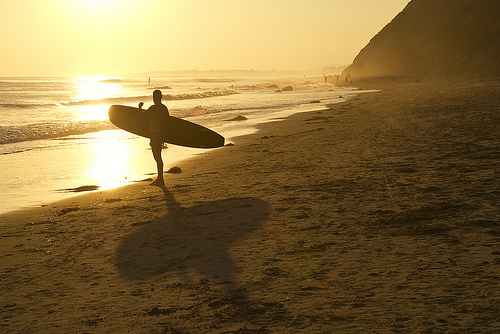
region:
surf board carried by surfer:
[99, 84, 230, 172]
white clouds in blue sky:
[4, 8, 33, 45]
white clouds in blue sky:
[28, 18, 78, 47]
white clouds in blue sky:
[256, 8, 297, 59]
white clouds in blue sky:
[137, 15, 196, 51]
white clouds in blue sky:
[298, 2, 344, 66]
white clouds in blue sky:
[191, 21, 248, 48]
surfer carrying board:
[107, 85, 233, 176]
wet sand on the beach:
[42, 214, 117, 253]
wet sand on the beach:
[187, 227, 306, 293]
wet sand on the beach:
[280, 134, 344, 219]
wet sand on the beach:
[57, 250, 132, 285]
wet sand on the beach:
[319, 80, 406, 135]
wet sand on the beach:
[303, 123, 440, 187]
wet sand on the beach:
[332, 173, 423, 231]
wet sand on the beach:
[208, 237, 275, 267]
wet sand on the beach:
[271, 196, 321, 226]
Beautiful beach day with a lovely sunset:
[22, 8, 465, 296]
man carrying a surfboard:
[110, 76, 225, 185]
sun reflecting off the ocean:
[79, 57, 132, 186]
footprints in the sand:
[296, 160, 432, 308]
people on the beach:
[317, 68, 361, 86]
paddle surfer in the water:
[144, 70, 163, 88]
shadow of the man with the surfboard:
[114, 181, 287, 328]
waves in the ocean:
[10, 98, 92, 129]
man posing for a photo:
[92, 78, 229, 190]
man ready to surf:
[113, 73, 224, 195]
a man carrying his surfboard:
[89, 73, 294, 203]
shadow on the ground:
[107, 155, 273, 309]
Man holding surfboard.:
[107, 89, 230, 188]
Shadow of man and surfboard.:
[115, 188, 267, 308]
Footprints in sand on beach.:
[274, 118, 499, 320]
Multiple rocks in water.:
[227, 75, 345, 135]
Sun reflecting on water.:
[53, 79, 130, 187]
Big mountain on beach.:
[340, 0, 490, 106]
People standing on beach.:
[320, 69, 359, 95]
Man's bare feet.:
[146, 179, 171, 190]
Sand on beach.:
[228, 84, 498, 324]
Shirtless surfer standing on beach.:
[109, 87, 226, 185]